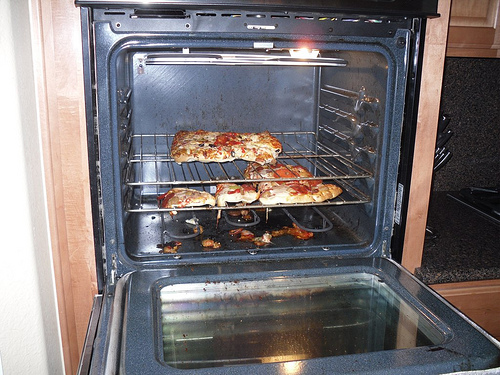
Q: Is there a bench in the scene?
A: No, there are no benches.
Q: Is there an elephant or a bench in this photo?
A: No, there are no benches or elephants.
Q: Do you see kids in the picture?
A: No, there are no kids.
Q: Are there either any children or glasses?
A: No, there are no children or glasses.